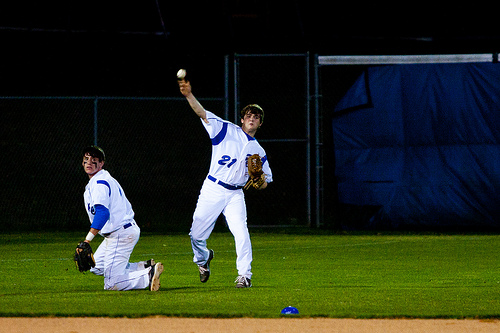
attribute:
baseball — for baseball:
[175, 65, 186, 79]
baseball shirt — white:
[77, 172, 143, 237]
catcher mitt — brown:
[248, 157, 267, 192]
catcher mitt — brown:
[73, 242, 97, 274]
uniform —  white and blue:
[187, 106, 277, 291]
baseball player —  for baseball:
[171, 63, 284, 293]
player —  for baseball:
[69, 142, 168, 300]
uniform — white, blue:
[200, 109, 261, 249]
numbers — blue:
[218, 155, 240, 167]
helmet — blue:
[278, 302, 300, 318]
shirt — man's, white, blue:
[205, 112, 272, 192]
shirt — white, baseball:
[202, 109, 272, 189]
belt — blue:
[207, 166, 250, 189]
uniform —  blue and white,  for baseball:
[185, 112, 270, 264]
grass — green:
[43, 159, 465, 313]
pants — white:
[178, 184, 263, 264]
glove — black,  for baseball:
[73, 240, 95, 277]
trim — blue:
[208, 117, 229, 149]